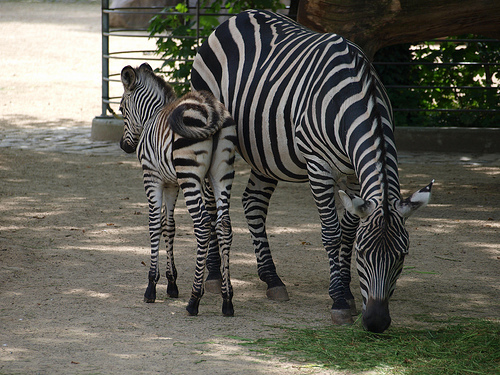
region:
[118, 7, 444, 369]
two zebras standing together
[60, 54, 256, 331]
small zebra standing on dirt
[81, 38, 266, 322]
small baby zebra standing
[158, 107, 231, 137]
curved tail of small zebra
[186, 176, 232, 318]
skinny hind legs of zebra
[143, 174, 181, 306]
skinny front legs of zebra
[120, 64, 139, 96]
brown and white ear of zebra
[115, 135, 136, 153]
black snout of zebra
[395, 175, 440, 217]
long white and black ears of zebra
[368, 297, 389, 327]
black snout of zebra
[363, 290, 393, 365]
This zebra has a black nose visible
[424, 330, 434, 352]
There is a patch of green grass here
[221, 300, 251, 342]
This zebra has a small hoof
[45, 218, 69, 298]
There is a patch of gravel that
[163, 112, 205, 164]
There is a small zebra tail here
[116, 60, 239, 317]
young zebra facing away from the camera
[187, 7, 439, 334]
adult zebra eating vegetation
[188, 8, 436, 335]
adult zebra facing frontward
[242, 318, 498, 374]
vegetation on the ground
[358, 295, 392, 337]
nose of adult zebra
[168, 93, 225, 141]
tail of young zebra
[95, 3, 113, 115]
corner post of railing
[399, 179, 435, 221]
left ear of adult zebra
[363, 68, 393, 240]
mane of adult zebra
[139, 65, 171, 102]
mane of young zebra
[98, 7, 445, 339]
Zebras on the ground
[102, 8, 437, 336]
Zebras are on the ground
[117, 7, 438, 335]
Zebras are standing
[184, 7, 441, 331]
Zebra is standing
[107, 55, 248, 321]
Baby zebra standing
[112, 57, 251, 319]
Baby zebra is standing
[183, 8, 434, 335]
Zebra eating hay off the ground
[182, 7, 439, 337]
Zebra is eating hay off the ground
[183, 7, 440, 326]
Zebra is standing in the dirt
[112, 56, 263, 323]
Baby zebra is standing in the dirt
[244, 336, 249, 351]
edge of a leg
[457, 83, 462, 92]
part of a bush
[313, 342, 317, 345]
part of a lawn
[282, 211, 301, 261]
part of a tail